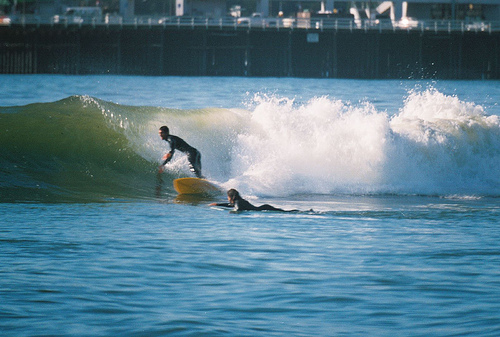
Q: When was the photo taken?
A: Daytime.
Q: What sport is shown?
A: Surfing.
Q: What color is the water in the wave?
A: Green.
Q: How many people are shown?
A: Two.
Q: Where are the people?
A: In the ocean.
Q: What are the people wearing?
A: Wetsuits.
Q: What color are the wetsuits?
A: Black.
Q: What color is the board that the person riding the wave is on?
A: Yellow.